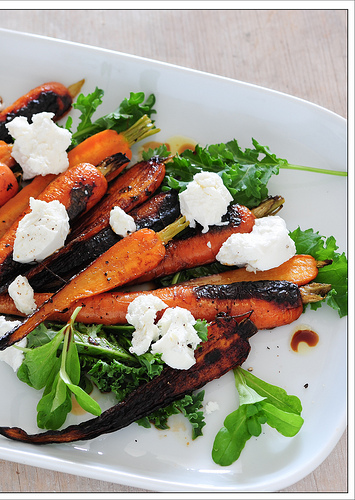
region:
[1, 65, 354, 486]
roasted carrots on white plate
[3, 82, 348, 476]
cheese sprinkled on roasted carrots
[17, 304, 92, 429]
leafy green herb on white plate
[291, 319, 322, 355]
small spot of sauce or juice on plate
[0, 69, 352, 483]
blackened root vegitables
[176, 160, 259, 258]
chunk of cheese on top of roasted carrot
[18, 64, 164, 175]
stems of carrots not cut off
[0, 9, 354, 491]
white plate full of roasted veggies on white table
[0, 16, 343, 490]
different sizes of root veggies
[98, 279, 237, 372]
two pieces of fresh cheese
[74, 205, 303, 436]
Grilled baby carrots on a white plate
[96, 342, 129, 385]
The kale is green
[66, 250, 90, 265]
This carrot is grilled black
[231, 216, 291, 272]
A soft white cheese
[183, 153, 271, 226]
Kale under the grilled carrots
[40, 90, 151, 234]
A plate of grilled carrots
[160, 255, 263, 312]
The carrots are orange and black in this dish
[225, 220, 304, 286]
A soft shite cheese on the carrots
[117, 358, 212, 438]
Green kale under the carrots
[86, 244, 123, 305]
Some grains of pepper on the carrot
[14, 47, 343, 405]
white plate of food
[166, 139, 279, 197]
leaves of green lettuce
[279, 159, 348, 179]
green stem of leaves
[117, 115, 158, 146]
stem on top of carrot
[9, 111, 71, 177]
clump of white cheese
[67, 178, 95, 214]
burn mark on carrot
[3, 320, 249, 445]
burned carrot with shriveled tip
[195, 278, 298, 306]
burn mark on skin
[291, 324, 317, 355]
oil drop on plate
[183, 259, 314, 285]
inside of sliced carrot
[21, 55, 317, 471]
white plate filled with food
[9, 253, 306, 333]
cooked small carrots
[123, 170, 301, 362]
white goat cheese on carrots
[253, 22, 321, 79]
very light wood table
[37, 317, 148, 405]
green lettuce under carrots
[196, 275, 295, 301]
area of carrot that got burnt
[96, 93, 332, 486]
white plate with a retagular shape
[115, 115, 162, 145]
stem of carrot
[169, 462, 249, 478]
light reflecting on plate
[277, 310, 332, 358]
brown sauce spilled on plate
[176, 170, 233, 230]
The plate contains cheese.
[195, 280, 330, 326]
The plate contains carrots.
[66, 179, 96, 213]
The carrots have been grilled.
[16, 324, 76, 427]
The plate contains greens.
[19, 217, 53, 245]
Seasoning is on the food.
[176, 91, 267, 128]
The plate is white.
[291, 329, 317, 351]
The plate contains dressing.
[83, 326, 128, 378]
Lettuce is on the table.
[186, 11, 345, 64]
The plate is on a table.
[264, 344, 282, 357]
Seasoning is on the plate.